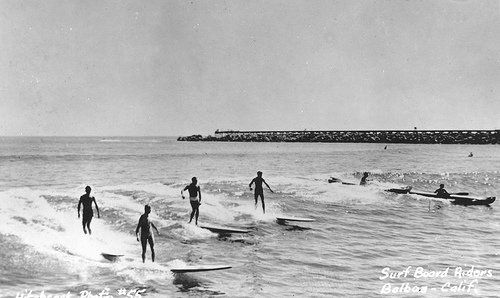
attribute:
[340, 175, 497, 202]
boat — Long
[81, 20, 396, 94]
skies — Light grey 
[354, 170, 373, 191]
person — boating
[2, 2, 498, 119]
sky — Blue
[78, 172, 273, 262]
surfers — Four 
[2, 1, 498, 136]
sky — Blue, clear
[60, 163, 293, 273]
people — surfing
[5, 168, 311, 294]
waves — white